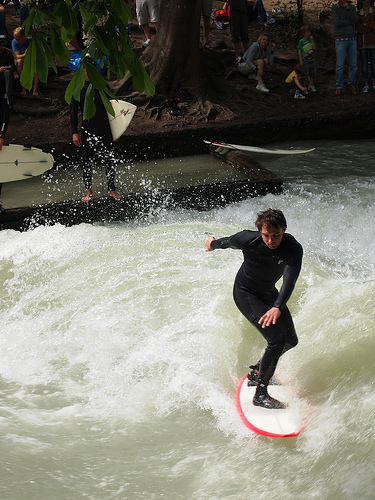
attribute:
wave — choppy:
[2, 190, 372, 498]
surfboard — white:
[236, 366, 312, 448]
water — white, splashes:
[1, 134, 374, 498]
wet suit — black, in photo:
[209, 231, 300, 383]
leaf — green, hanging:
[76, 77, 104, 126]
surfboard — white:
[0, 142, 55, 187]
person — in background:
[6, 24, 28, 93]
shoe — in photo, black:
[249, 385, 288, 416]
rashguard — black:
[212, 228, 312, 309]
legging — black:
[255, 327, 288, 385]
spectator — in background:
[323, 4, 364, 102]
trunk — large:
[100, 2, 231, 126]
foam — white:
[2, 222, 112, 278]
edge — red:
[236, 369, 307, 448]